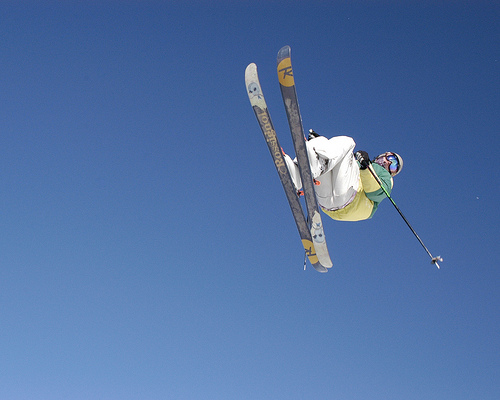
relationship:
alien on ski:
[283, 136, 400, 222] [243, 60, 327, 272]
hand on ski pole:
[353, 147, 373, 169] [362, 157, 456, 276]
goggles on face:
[380, 148, 402, 175] [376, 155, 399, 172]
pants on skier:
[294, 132, 362, 212] [277, 135, 405, 223]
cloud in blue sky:
[12, 228, 152, 390] [0, 0, 497, 400]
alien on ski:
[242, 78, 268, 110] [241, 58, 331, 278]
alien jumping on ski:
[283, 136, 400, 222] [243, 60, 327, 272]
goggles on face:
[387, 155, 398, 173] [372, 149, 402, 178]